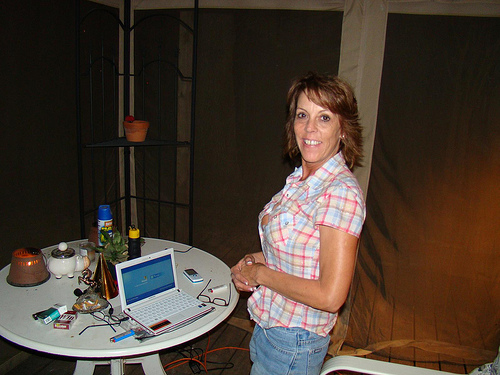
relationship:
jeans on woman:
[248, 313, 333, 374] [228, 72, 369, 374]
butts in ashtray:
[80, 301, 92, 307] [74, 292, 109, 312]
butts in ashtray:
[84, 300, 92, 307] [74, 292, 109, 312]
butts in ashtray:
[93, 299, 100, 307] [74, 292, 109, 312]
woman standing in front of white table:
[228, 72, 369, 374] [1, 232, 237, 374]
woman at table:
[219, 60, 359, 372] [0, 232, 245, 372]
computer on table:
[112, 248, 213, 333] [0, 232, 245, 372]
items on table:
[23, 203, 220, 347] [53, 236, 211, 373]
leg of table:
[142, 356, 164, 373] [6, 227, 245, 355]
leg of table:
[109, 362, 129, 374] [6, 227, 245, 355]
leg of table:
[69, 359, 91, 374] [6, 227, 245, 355]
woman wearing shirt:
[228, 72, 369, 374] [246, 159, 369, 333]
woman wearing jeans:
[228, 72, 369, 374] [248, 313, 333, 374]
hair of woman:
[288, 79, 361, 158] [228, 72, 369, 374]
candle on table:
[56, 241, 71, 253] [0, 232, 245, 372]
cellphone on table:
[183, 268, 203, 283] [0, 232, 245, 372]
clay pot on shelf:
[121, 114, 151, 144] [69, 0, 201, 250]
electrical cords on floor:
[167, 340, 248, 370] [176, 309, 251, 366]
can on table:
[97, 205, 111, 245] [0, 232, 245, 372]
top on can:
[99, 205, 110, 218] [97, 205, 111, 245]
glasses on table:
[198, 261, 264, 338] [6, 190, 266, 352]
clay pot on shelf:
[120, 114, 150, 149] [74, 128, 191, 156]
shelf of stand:
[74, 128, 191, 156] [83, 1, 213, 221]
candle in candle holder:
[26, 259, 31, 265] [6, 245, 49, 288]